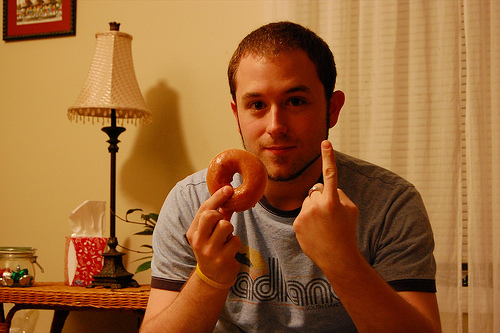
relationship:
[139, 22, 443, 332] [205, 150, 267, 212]
man holding donut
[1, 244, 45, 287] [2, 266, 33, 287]
jar with wrapped candy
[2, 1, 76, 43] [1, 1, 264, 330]
picture on wall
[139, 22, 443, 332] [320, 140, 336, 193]
man holding up finger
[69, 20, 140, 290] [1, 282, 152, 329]
lamp on table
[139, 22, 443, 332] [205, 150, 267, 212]
man holds a donut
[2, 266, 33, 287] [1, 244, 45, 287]
candy in a jar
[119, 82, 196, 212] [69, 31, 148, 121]
shadow of lamp shade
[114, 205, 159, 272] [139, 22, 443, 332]
plant behind man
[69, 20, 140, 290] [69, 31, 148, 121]
lamp with a beige lamp shade